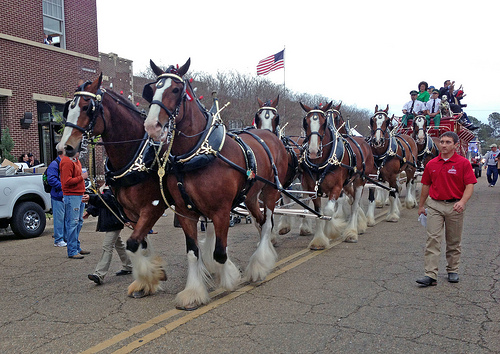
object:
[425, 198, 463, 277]
pants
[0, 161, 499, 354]
floor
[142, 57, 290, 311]
horse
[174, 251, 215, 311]
leg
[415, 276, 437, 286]
shoe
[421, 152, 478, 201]
shirt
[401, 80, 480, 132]
people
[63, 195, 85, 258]
pants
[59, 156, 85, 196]
sweater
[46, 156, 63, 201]
shirt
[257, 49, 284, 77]
flag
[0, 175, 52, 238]
truck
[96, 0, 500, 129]
sky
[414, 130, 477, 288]
man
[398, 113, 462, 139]
carriage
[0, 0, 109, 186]
wall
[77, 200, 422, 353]
line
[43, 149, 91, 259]
people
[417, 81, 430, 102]
woman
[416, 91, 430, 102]
green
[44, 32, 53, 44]
person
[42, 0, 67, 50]
window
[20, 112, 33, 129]
object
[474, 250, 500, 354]
crack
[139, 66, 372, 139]
tree